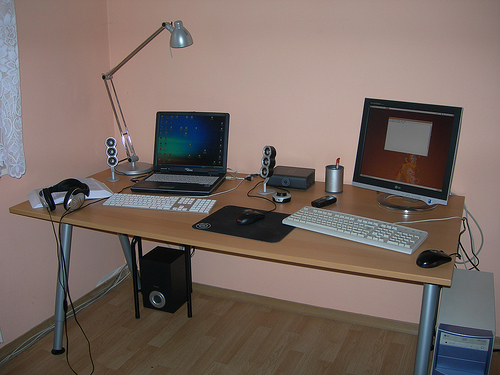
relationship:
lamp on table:
[94, 14, 194, 180] [8, 150, 479, 372]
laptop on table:
[124, 99, 233, 193] [54, 149, 292, 261]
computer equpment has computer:
[38, 172, 345, 207] [133, 105, 231, 191]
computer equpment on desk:
[38, 172, 345, 207] [7, 160, 465, 372]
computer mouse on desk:
[415, 243, 455, 271] [7, 160, 465, 372]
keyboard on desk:
[281, 205, 429, 254] [7, 160, 465, 372]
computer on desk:
[352, 96, 465, 206] [7, 160, 465, 372]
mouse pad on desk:
[192, 202, 299, 246] [7, 160, 465, 372]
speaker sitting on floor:
[127, 243, 200, 330] [4, 265, 497, 371]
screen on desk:
[352, 94, 467, 208] [7, 160, 465, 372]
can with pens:
[322, 159, 344, 196] [331, 154, 347, 166]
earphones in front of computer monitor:
[38, 178, 95, 375] [346, 88, 469, 208]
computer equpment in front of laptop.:
[102, 193, 217, 214] [140, 107, 226, 191]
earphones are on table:
[41, 167, 98, 373] [29, 65, 494, 345]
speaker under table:
[139, 245, 187, 313] [31, 139, 461, 371]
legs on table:
[36, 224, 448, 372] [27, 152, 467, 348]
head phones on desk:
[35, 176, 92, 215] [7, 160, 465, 372]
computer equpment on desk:
[102, 193, 217, 214] [7, 160, 465, 372]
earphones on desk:
[38, 178, 95, 375] [7, 160, 465, 372]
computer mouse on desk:
[415, 249, 452, 269] [4, 141, 469, 361]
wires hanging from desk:
[440, 196, 494, 277] [106, 129, 492, 327]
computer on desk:
[130, 111, 230, 196] [50, 137, 455, 321]